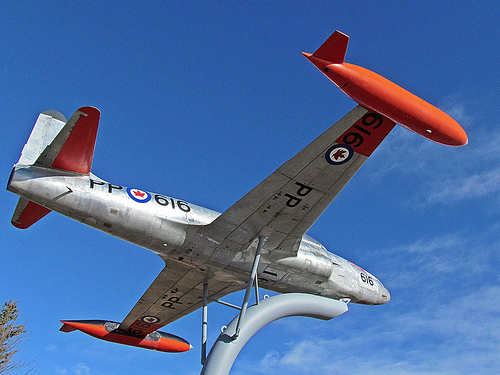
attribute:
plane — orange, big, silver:
[159, 210, 261, 274]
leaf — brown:
[5, 307, 14, 318]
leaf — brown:
[10, 331, 12, 337]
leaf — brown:
[3, 339, 6, 345]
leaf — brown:
[3, 332, 6, 339]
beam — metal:
[262, 307, 320, 311]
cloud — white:
[407, 315, 482, 349]